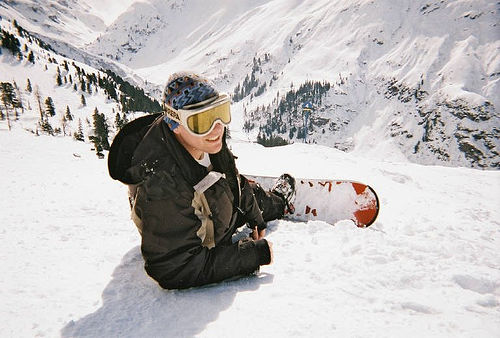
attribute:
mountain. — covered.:
[6, 0, 500, 336]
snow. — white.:
[6, 5, 499, 336]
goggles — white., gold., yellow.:
[170, 93, 234, 135]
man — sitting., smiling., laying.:
[108, 73, 294, 287]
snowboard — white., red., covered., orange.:
[239, 173, 382, 230]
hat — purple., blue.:
[157, 71, 217, 134]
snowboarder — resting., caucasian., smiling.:
[108, 71, 380, 293]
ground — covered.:
[13, 138, 494, 338]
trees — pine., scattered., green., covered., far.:
[5, 19, 333, 153]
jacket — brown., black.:
[113, 120, 273, 280]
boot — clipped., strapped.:
[271, 173, 299, 222]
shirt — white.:
[194, 152, 220, 175]